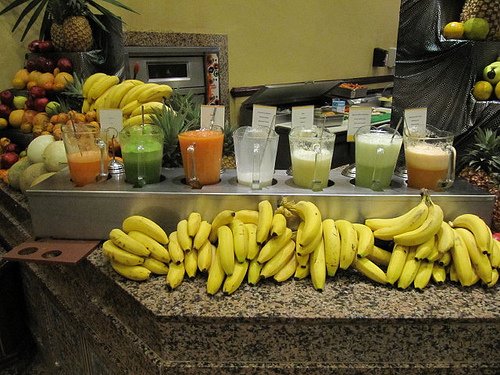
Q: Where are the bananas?
A: On the counter.